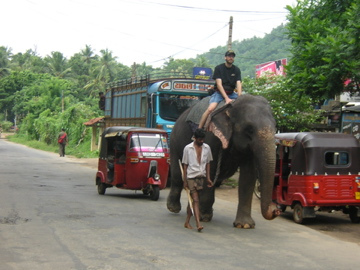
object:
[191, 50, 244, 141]
man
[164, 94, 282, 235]
elephant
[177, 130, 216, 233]
man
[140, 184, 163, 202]
wheel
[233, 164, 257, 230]
leg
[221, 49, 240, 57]
hat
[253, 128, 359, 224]
cab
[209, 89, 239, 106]
jeans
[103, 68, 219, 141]
bus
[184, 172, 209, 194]
shorts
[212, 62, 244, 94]
shirt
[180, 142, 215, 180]
shirt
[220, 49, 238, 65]
head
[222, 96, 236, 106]
arm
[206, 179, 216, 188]
hand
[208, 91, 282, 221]
head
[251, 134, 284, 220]
trunk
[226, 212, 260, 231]
foot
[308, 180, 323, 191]
light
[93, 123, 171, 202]
car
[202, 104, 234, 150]
ear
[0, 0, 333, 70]
sky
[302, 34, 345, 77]
leaves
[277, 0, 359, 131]
tree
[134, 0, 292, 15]
wires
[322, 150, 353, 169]
window